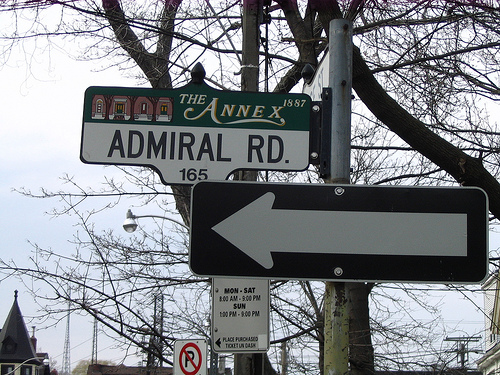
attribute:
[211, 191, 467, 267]
arrow — large, white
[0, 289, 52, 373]
building — pointy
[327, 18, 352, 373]
pole — gray, metallic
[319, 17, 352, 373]
pole — metallic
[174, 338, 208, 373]
sign — no parking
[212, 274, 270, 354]
sign — white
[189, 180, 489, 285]
sign — black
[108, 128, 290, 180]
writing — black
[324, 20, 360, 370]
pole — metal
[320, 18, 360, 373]
pole — metal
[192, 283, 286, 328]
sign on pole — white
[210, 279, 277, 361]
white street sign — green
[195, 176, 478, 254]
arrow on a black sig — white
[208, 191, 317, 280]
arrow on a sign — white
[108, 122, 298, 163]
admiral rd. sign — green, white